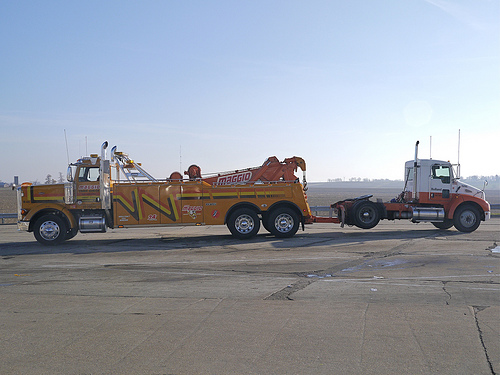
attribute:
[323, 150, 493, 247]
cab — red, white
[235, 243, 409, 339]
road — cement, wet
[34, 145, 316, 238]
tow truck — orange, parked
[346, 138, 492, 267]
cab — towed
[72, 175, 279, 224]
stripes — yellow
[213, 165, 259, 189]
name — red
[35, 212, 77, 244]
hubcaps — silver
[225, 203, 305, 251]
tires — black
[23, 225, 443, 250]
shadows — on ground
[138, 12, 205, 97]
sky — blue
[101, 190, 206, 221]
lines — red, yellow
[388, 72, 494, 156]
sun — shining